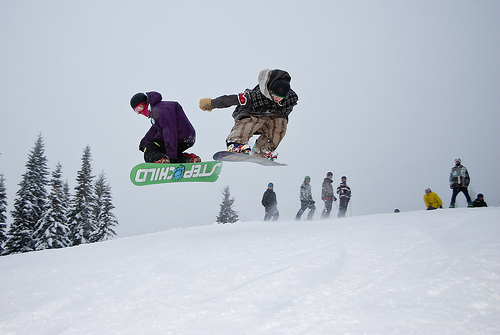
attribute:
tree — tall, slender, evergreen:
[65, 147, 97, 244]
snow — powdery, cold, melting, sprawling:
[10, 242, 498, 334]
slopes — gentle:
[1, 201, 499, 334]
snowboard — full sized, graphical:
[127, 163, 225, 187]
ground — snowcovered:
[335, 152, 414, 209]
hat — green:
[266, 69, 290, 98]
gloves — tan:
[203, 97, 215, 110]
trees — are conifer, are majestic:
[2, 126, 122, 257]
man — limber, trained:
[409, 119, 486, 216]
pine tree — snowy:
[213, 184, 240, 224]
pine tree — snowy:
[66, 145, 98, 243]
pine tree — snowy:
[2, 130, 51, 255]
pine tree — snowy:
[32, 162, 73, 253]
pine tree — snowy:
[96, 182, 119, 243]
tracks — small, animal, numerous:
[171, 220, 391, 330]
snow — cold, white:
[2, 203, 497, 333]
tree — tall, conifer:
[3, 134, 54, 256]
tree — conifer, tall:
[28, 164, 67, 249]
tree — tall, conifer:
[85, 171, 123, 237]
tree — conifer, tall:
[62, 142, 102, 243]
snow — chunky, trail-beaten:
[11, 157, 118, 243]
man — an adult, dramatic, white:
[441, 155, 478, 217]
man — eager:
[261, 182, 280, 221]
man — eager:
[292, 175, 317, 219]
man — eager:
[318, 168, 336, 217]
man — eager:
[335, 172, 350, 219]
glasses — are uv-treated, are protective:
[111, 87, 171, 118]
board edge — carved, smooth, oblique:
[173, 177, 198, 184]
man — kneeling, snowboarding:
[126, 89, 209, 161]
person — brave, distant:
[420, 187, 442, 208]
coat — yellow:
[424, 192, 441, 207]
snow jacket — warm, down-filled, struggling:
[422, 192, 443, 207]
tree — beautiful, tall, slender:
[32, 160, 72, 249]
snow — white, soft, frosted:
[32, 162, 72, 249]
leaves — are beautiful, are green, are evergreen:
[34, 162, 74, 251]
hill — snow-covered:
[50, 214, 250, 333]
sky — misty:
[69, 142, 99, 181]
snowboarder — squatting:
[125, 91, 211, 164]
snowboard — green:
[129, 160, 221, 183]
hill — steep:
[92, 210, 484, 326]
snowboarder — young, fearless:
[128, 90, 204, 158]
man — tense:
[133, 93, 198, 163]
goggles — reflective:
[129, 100, 149, 111]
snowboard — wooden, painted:
[121, 159, 226, 181]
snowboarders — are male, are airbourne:
[103, 52, 315, 180]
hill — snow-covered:
[3, 207, 293, 322]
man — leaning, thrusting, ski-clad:
[203, 52, 302, 170]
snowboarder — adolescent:
[125, 82, 224, 192]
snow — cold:
[291, 203, 483, 274]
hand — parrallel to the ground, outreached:
[197, 96, 220, 111]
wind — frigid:
[13, 11, 481, 222]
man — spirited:
[418, 189, 447, 213]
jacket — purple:
[149, 99, 192, 154]